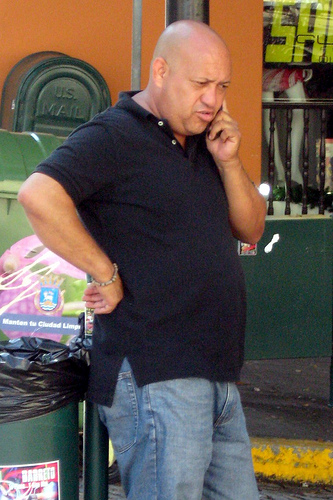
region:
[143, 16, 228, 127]
man with a bald head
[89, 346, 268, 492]
man with blue jeans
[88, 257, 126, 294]
man with a band on its wrist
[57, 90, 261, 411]
man wearing a blue shirt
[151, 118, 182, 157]
two buttons on a shirt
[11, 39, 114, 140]
Post office mail box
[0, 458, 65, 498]
sticker on a garbage can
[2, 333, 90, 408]
plastic bag in a garbage can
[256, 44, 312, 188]
manque in the window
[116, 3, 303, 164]
a bald man on a cell phone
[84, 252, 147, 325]
a bracelet on the wrist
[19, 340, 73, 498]
a garbage can next to the man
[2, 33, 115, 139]
a mail box in the background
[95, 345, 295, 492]
the blue jeans on the man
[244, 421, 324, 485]
yellow faded paint on curb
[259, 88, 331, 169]
a fence in background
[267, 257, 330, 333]
a green wall behind the man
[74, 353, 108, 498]
a green pole behind the man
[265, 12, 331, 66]
yellow lettering on a sign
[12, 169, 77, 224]
the elbow is bent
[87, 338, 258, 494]
the jeans are blue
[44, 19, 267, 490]
the man is on the phone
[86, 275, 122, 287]
the man is wearing a bracelet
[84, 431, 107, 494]
the pole is black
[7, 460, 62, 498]
the sticker is on the garbage can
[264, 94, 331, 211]
the hand rail is brown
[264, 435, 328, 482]
the curb is yellow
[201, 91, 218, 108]
the man has a nose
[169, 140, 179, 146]
the shirt has a button on it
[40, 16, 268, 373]
man talking on the phone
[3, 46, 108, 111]
green us mail box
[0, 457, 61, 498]
sticker on the garbage can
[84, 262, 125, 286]
band on the wrist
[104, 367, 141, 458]
pocket on the blue jeans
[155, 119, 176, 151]
buttons on the collar of the shirt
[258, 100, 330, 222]
railing on the building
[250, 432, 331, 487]
yellow on the sidewalk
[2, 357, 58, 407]
black garbage bag in the can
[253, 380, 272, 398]
pebbles on the ground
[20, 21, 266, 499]
a man on his cell phone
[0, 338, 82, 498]
a trash can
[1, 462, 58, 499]
a red sticker on the green trash can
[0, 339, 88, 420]
black plastic bag in the trash can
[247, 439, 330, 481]
yellow painted curb on the street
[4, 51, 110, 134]
a green mailbox behind the man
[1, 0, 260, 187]
an orange building behind the man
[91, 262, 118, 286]
bracelet on the man's wrist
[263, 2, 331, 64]
yellow sale sign in the window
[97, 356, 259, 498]
the man's faded blue jeans